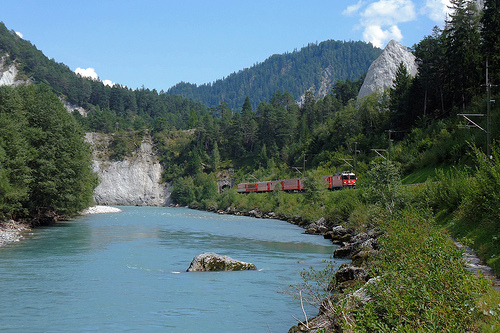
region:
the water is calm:
[21, 260, 88, 321]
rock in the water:
[179, 246, 260, 279]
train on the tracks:
[225, 166, 368, 201]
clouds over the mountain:
[365, 5, 400, 55]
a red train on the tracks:
[229, 168, 368, 192]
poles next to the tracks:
[363, 88, 493, 160]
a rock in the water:
[185, 248, 257, 269]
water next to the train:
[3, 178, 352, 331]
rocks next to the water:
[332, 223, 377, 265]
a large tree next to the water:
[6, 89, 93, 214]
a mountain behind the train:
[138, 56, 401, 114]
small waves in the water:
[144, 208, 220, 231]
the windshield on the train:
[342, 175, 357, 178]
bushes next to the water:
[381, 217, 451, 332]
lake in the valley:
[26, 170, 333, 330]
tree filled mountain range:
[152, 58, 254, 133]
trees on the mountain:
[109, 73, 159, 135]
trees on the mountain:
[60, 66, 100, 116]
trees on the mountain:
[10, 24, 49, 71]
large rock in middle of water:
[183, 234, 277, 294]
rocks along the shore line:
[269, 214, 363, 322]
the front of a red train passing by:
[326, 165, 368, 197]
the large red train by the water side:
[237, 164, 364, 196]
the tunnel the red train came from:
[215, 170, 236, 202]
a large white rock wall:
[76, 127, 187, 219]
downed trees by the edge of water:
[14, 198, 74, 225]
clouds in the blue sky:
[337, 1, 433, 44]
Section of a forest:
[6, 77, 113, 257]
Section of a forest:
[52, 95, 100, 222]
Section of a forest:
[0, 22, 41, 72]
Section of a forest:
[29, 34, 79, 102]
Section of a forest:
[74, 64, 120, 106]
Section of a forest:
[114, 74, 162, 133]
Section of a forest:
[166, 67, 228, 137]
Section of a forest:
[199, 70, 271, 142]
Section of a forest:
[227, 95, 304, 161]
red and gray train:
[233, 173, 365, 198]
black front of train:
[337, 166, 364, 183]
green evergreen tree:
[30, 85, 101, 230]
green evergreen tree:
[2, 83, 39, 229]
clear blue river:
[7, 201, 347, 330]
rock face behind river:
[80, 125, 170, 210]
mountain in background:
[5, 25, 395, 140]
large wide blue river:
[1, 203, 356, 332]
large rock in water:
[184, 251, 259, 273]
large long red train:
[219, 169, 358, 194]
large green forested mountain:
[161, 39, 386, 107]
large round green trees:
[0, 83, 100, 225]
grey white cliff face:
[84, 134, 177, 208]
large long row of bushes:
[335, 199, 499, 330]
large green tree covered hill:
[0, 22, 211, 132]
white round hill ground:
[81, 202, 123, 212]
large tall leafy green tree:
[0, 83, 29, 219]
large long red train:
[229, 170, 361, 195]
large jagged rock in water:
[183, 249, 260, 276]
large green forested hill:
[179, 74, 357, 176]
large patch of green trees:
[4, 81, 104, 233]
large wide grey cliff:
[87, 128, 172, 207]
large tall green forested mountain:
[169, 37, 385, 120]